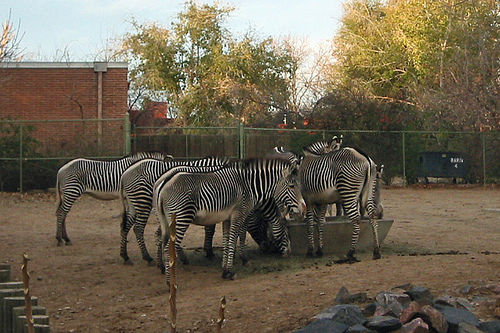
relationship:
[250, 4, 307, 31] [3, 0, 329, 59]
clouds are floating in sky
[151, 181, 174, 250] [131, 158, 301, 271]
tail attached to zebra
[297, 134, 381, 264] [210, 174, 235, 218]
zebra have stripes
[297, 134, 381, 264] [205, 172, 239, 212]
zebra have stripes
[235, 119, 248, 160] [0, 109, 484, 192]
pole of fence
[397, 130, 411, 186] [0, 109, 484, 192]
pole of fence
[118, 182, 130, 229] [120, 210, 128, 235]
tail with tip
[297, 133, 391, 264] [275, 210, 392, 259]
zebra eating at metal bin